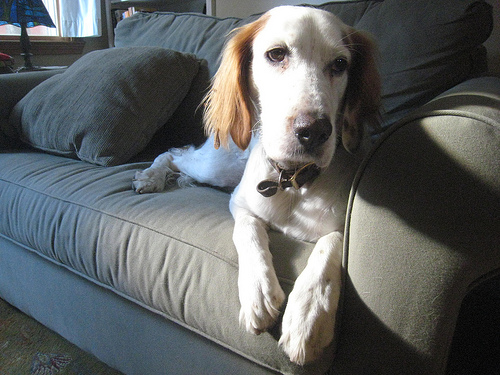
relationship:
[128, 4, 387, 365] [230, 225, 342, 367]
dog with its paws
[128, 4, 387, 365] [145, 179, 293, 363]
dog sitting in sun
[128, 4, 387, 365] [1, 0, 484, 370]
dog lying on a couch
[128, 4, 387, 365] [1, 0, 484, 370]
dog lying down on a couch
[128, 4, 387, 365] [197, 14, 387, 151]
dog with ears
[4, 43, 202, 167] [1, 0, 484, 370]
pillow on couch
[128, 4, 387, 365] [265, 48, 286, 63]
dog with eye